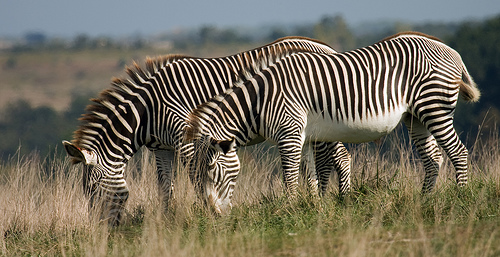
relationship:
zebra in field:
[179, 31, 480, 228] [6, 203, 500, 255]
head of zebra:
[174, 131, 242, 217] [179, 31, 480, 228]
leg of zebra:
[278, 114, 307, 207] [179, 31, 480, 228]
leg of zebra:
[406, 117, 437, 198] [179, 31, 480, 228]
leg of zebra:
[416, 102, 471, 193] [179, 31, 480, 228]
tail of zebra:
[461, 61, 481, 105] [179, 31, 480, 228]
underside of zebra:
[304, 105, 410, 144] [179, 31, 480, 228]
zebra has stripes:
[179, 31, 480, 228] [303, 46, 409, 120]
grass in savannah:
[246, 201, 493, 246] [6, 203, 500, 255]